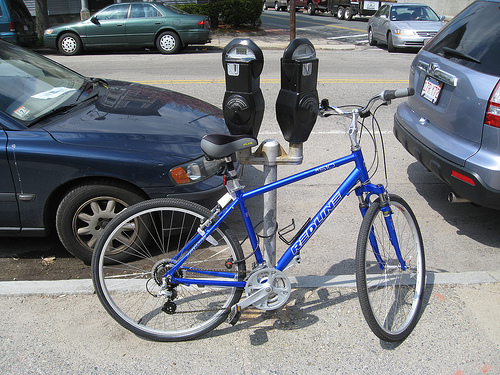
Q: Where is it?
A: This is at the road.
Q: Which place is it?
A: It is a road.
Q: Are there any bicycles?
A: Yes, there is a bicycle.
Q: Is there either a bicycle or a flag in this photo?
A: Yes, there is a bicycle.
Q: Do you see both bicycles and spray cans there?
A: No, there is a bicycle but no spray cans.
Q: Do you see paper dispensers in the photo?
A: No, there are no paper dispensers.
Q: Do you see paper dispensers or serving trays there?
A: No, there are no paper dispensers or serving trays.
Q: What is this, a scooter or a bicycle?
A: This is a bicycle.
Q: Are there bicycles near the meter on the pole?
A: Yes, there is a bicycle near the meter.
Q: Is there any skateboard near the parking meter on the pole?
A: No, there is a bicycle near the meter.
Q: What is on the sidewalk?
A: The bicycle is on the sidewalk.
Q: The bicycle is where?
A: The bicycle is on the side walk.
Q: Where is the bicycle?
A: The bicycle is on the side walk.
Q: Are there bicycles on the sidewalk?
A: Yes, there is a bicycle on the sidewalk.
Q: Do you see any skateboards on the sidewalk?
A: No, there is a bicycle on the sidewalk.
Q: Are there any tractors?
A: No, there are no tractors.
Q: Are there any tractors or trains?
A: No, there are no tractors or trains.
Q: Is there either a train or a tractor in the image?
A: No, there are no tractors or trains.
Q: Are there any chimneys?
A: No, there are no chimneys.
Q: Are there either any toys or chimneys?
A: No, there are no chimneys or toys.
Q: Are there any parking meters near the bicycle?
A: Yes, there is a parking meter near the bicycle.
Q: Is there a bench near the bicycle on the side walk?
A: No, there is a parking meter near the bicycle.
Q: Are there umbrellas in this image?
A: No, there are no umbrellas.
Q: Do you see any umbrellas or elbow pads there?
A: No, there are no umbrellas or elbow pads.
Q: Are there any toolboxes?
A: No, there are no toolboxes.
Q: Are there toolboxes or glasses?
A: No, there are no toolboxes or glasses.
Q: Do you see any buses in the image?
A: No, there are no buses.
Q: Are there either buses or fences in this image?
A: No, there are no buses or fences.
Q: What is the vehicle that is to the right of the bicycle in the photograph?
A: The vehicle is a car.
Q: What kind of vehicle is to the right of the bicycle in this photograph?
A: The vehicle is a car.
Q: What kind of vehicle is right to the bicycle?
A: The vehicle is a car.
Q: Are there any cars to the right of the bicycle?
A: Yes, there is a car to the right of the bicycle.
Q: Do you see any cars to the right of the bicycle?
A: Yes, there is a car to the right of the bicycle.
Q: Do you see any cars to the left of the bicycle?
A: No, the car is to the right of the bicycle.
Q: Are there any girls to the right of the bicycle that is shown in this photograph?
A: No, there is a car to the right of the bicycle.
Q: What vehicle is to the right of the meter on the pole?
A: The vehicle is a car.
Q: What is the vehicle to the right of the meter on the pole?
A: The vehicle is a car.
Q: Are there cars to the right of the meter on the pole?
A: Yes, there is a car to the right of the meter.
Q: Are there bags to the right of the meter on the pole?
A: No, there is a car to the right of the meter.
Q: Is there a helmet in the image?
A: No, there are no helmets.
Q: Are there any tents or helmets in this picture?
A: No, there are no helmets or tents.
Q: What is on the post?
A: The parking meter is on the post.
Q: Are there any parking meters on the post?
A: Yes, there is a parking meter on the post.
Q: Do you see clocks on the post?
A: No, there is a parking meter on the post.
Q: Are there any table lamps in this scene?
A: No, there are no table lamps.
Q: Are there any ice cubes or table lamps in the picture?
A: No, there are no table lamps or ice cubes.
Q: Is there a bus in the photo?
A: No, there are no buses.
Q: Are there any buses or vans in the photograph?
A: No, there are no buses or vans.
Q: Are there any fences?
A: No, there are no fences.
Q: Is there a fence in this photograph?
A: No, there are no fences.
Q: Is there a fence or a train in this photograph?
A: No, there are no fences or trains.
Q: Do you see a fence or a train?
A: No, there are no fences or trains.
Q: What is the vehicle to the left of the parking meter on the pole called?
A: The vehicle is a car.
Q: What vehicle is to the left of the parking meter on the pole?
A: The vehicle is a car.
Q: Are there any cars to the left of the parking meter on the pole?
A: Yes, there is a car to the left of the parking meter.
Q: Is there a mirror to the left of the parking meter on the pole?
A: No, there is a car to the left of the meter.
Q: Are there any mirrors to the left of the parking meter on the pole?
A: No, there is a car to the left of the meter.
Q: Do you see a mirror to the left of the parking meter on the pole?
A: No, there is a car to the left of the meter.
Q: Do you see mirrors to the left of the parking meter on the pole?
A: No, there is a car to the left of the meter.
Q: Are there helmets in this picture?
A: No, there are no helmets.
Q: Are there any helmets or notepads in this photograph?
A: No, there are no helmets or notepads.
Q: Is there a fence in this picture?
A: No, there are no fences.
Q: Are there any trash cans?
A: No, there are no trash cans.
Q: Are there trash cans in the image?
A: No, there are no trash cans.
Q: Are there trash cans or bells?
A: No, there are no trash cans or bells.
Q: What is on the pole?
A: The parking meter is on the pole.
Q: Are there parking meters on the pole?
A: Yes, there is a parking meter on the pole.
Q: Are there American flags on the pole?
A: No, there is a parking meter on the pole.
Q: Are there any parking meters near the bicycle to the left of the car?
A: Yes, there is a parking meter near the bicycle.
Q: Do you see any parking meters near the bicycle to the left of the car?
A: Yes, there is a parking meter near the bicycle.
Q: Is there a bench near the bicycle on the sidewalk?
A: No, there is a parking meter near the bicycle.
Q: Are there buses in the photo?
A: No, there are no buses.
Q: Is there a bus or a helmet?
A: No, there are no buses or helmets.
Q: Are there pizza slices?
A: No, there are no pizza slices.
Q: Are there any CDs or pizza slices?
A: No, there are no pizza slices or cds.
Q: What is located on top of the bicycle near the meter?
A: The seat is on top of the bicycle.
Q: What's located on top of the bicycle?
A: The seat is on top of the bicycle.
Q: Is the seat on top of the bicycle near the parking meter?
A: Yes, the seat is on top of the bicycle.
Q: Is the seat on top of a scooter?
A: No, the seat is on top of the bicycle.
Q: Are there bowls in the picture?
A: No, there are no bowls.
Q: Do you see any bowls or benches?
A: No, there are no bowls or benches.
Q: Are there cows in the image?
A: No, there are no cows.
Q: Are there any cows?
A: No, there are no cows.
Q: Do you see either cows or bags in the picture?
A: No, there are no cows or bags.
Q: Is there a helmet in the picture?
A: No, there are no helmets.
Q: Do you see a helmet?
A: No, there are no helmets.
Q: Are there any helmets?
A: No, there are no helmets.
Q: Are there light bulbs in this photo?
A: No, there are no light bulbs.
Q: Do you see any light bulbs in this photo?
A: No, there are no light bulbs.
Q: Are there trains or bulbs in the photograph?
A: No, there are no bulbs or trains.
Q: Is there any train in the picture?
A: No, there are no trains.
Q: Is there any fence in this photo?
A: No, there are no fences.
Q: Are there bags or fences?
A: No, there are no fences or bags.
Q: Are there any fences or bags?
A: No, there are no fences or bags.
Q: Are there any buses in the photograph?
A: No, there are no buses.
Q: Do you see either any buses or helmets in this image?
A: No, there are no buses or helmets.